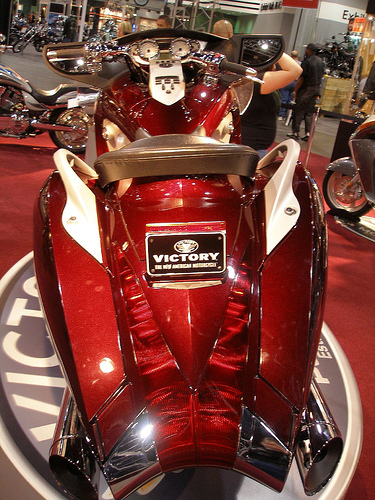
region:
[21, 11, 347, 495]
A red motorcycle.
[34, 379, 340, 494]
Two chrome exhaust pipes.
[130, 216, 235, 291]
A metal plate with the manufacturer's name on it.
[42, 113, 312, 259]
Two handles.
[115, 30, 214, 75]
The motorcycle's instrument panel.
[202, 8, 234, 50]
A bald man.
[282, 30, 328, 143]
The man is dressed in all black.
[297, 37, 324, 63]
The man is wearing a hat.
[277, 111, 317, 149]
The man is wearing sneakers.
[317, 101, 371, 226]
A scooter.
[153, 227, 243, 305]
the word victory on the bike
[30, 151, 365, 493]
a red motorcylce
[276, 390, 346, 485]
right exhaust of the bike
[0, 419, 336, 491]
the exhausts of the bike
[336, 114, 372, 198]
the tire of the motorcycle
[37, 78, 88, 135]
a grey bike in the back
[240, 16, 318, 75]
rear view mirror of the bike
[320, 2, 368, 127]
the sign for the exhibit hall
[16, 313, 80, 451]
the ground for the bike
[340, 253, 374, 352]
red carpet for the event hall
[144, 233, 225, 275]
License plate says victory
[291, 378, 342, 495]
muffler made of chrome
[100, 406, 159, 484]
reflection of the light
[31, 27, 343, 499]
the motorcycle is red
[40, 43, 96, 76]
side mirror on the motorcycle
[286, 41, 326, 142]
man in black shirt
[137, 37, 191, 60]
dials are white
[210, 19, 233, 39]
a man's bald head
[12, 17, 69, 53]
black motorcycle in the background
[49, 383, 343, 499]
two chrome exhaust pipes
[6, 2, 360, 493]
A scene indoors.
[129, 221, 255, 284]
License plate with the word Victory on it.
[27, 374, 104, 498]
An exhaust pipe.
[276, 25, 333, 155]
A person in black walking.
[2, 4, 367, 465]
A motorcycle exhibit.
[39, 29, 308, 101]
Motorcycle's handlebars and mirrors.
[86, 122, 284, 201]
A brown seat.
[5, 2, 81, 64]
Group of motorcycles in the distance.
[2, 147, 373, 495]
A patch of red carpet.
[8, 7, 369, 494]
Red motorcycle on exhibition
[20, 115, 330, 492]
Back of motorcycle is fancy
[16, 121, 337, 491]
Back of motorcycle is red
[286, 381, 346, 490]
Exhaust pipe on right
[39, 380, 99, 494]
Exhaust pipe on left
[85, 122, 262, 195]
Sit of motorcycle is red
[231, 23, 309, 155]
Person wearing a black hat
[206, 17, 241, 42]
Person has bald head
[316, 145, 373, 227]
Front wheel of motorcycle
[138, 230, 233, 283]
Letter on back of motorcycle says "Victory"